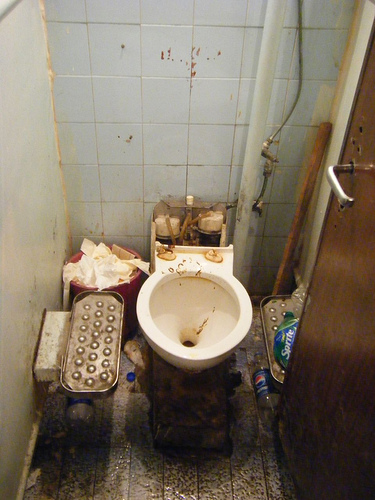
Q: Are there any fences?
A: No, there are no fences.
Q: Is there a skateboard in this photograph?
A: No, there are no skateboards.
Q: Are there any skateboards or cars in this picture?
A: No, there are no skateboards or cars.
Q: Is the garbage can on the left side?
A: Yes, the garbage can is on the left of the image.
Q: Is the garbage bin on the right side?
A: No, the garbage bin is on the left of the image.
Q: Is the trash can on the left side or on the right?
A: The trash can is on the left of the image.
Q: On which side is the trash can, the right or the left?
A: The trash can is on the left of the image.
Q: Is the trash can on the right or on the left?
A: The trash can is on the left of the image.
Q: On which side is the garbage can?
A: The garbage can is on the left of the image.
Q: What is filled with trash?
A: The trash bin is filled with trash.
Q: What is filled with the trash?
A: The trash bin is filled with trash.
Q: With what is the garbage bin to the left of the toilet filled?
A: The garbage can is filled with trash.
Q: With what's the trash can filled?
A: The garbage can is filled with trash.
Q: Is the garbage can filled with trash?
A: Yes, the garbage can is filled with trash.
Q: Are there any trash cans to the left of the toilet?
A: Yes, there is a trash can to the left of the toilet.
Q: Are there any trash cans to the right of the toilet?
A: No, the trash can is to the left of the toilet.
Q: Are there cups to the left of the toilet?
A: No, there is a trash can to the left of the toilet.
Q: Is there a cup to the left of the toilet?
A: No, there is a trash can to the left of the toilet.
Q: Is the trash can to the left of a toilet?
A: Yes, the trash can is to the left of a toilet.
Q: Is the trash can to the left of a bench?
A: No, the trash can is to the left of a toilet.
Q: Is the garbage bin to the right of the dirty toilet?
A: No, the garbage bin is to the left of the toilet.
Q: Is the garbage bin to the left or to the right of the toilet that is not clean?
A: The garbage bin is to the left of the toilet.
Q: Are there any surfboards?
A: No, there are no surfboards.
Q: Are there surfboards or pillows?
A: No, there are no surfboards or pillows.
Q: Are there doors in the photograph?
A: Yes, there is a door.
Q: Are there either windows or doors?
A: Yes, there is a door.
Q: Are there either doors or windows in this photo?
A: Yes, there is a door.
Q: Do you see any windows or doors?
A: Yes, there is a door.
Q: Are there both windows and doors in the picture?
A: No, there is a door but no windows.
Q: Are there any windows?
A: No, there are no windows.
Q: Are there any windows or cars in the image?
A: No, there are no windows or cars.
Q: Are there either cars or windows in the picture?
A: No, there are no windows or cars.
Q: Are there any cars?
A: No, there are no cars.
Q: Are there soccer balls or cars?
A: No, there are no cars or soccer balls.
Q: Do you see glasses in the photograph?
A: No, there are no glasses.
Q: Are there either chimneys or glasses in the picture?
A: No, there are no glasses or chimneys.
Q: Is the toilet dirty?
A: Yes, the toilet is dirty.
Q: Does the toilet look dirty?
A: Yes, the toilet is dirty.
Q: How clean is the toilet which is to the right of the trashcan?
A: The toilet is dirty.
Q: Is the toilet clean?
A: No, the toilet is dirty.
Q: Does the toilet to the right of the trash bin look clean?
A: No, the toilet is dirty.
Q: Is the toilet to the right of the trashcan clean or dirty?
A: The toilet is dirty.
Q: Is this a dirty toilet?
A: Yes, this is a dirty toilet.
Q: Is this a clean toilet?
A: No, this is a dirty toilet.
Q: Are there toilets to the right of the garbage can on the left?
A: Yes, there is a toilet to the right of the garbage bin.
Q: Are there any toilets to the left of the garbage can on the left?
A: No, the toilet is to the right of the trashcan.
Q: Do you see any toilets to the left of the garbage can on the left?
A: No, the toilet is to the right of the trashcan.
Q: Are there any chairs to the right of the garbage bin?
A: No, there is a toilet to the right of the garbage bin.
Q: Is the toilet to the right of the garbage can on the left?
A: Yes, the toilet is to the right of the trash can.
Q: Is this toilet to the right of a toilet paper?
A: No, the toilet is to the right of the trash can.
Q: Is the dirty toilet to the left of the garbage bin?
A: No, the toilet is to the right of the garbage bin.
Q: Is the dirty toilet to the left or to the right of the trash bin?
A: The toilet is to the right of the trash bin.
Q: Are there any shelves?
A: No, there are no shelves.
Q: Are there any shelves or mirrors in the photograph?
A: No, there are no shelves or mirrors.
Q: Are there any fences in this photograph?
A: No, there are no fences.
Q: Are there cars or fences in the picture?
A: No, there are no fences or cars.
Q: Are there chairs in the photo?
A: No, there are no chairs.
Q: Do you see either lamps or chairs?
A: No, there are no chairs or lamps.